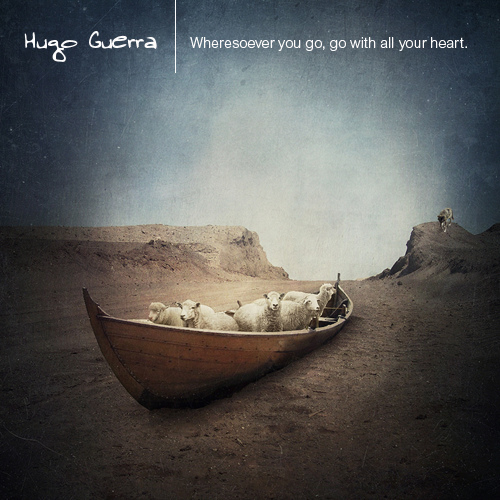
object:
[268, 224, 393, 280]
opening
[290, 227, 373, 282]
pass through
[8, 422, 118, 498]
road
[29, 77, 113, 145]
cloud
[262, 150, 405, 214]
skies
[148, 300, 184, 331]
sheep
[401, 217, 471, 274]
cliff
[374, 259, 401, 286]
rock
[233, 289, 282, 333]
animal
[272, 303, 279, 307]
nose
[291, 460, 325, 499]
dirt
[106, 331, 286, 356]
lines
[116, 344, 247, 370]
lines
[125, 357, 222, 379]
lines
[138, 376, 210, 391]
lines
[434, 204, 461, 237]
wolf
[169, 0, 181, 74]
line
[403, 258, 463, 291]
ridges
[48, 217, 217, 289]
land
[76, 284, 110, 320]
boat tip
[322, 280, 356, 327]
open side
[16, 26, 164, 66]
name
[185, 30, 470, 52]
quote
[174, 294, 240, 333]
sheep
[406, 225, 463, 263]
rock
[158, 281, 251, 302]
road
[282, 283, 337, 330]
lamb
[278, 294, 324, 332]
lamb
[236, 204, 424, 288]
earth depression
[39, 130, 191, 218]
sky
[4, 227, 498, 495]
partition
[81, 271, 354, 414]
boat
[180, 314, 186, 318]
nose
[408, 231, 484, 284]
background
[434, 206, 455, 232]
object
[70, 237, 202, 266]
row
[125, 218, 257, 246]
row